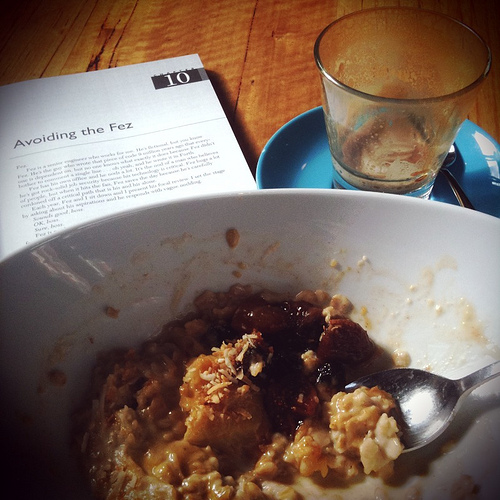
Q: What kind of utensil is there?
A: A spoon.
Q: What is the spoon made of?
A: Metal.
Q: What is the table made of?
A: Wood.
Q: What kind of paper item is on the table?
A: A book.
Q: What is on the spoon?
A: Food.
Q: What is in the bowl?
A: Nuts and fruit.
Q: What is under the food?
A: A round white bowl.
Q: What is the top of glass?
A: A glass rim.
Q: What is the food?
A: A cake with berry's.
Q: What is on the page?
A: Letters and numbers.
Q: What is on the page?
A: Writing.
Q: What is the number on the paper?
A: 10.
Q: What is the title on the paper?
A: Avoiding the Fez.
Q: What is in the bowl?
A: Food.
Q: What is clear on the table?
A: Glass.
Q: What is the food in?
A: Bowl.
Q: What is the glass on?
A: Saucer.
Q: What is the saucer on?
A: Table.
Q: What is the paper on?
A: Table.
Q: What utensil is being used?
A: Spoon.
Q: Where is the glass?
A: On a plate.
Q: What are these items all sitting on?
A: Table.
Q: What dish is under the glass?
A: Plate.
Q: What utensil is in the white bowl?
A: Spoon.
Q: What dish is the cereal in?
A: Bowl.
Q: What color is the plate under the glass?
A: Blue.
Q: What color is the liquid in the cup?
A: Brown.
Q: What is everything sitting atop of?
A: A table.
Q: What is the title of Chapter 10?
A: Avoiding the Fez.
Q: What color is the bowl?
A: White.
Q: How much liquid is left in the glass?
A: None.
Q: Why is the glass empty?
A: The contents had been consumed.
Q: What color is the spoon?
A: Silver.